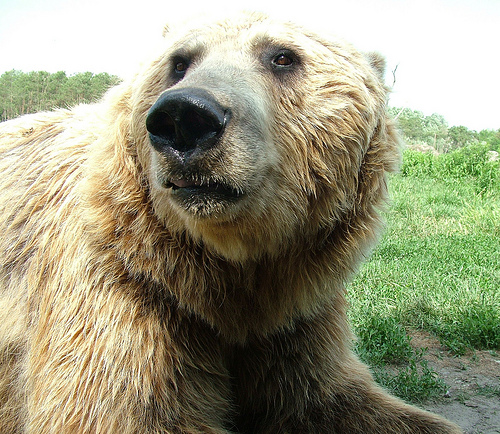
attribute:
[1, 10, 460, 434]
bear — brown, large, staring, curious, looking, wild, nice looking, cute, animal, alone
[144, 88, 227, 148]
nose — large, black, wet, big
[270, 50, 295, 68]
eye — small, brown, left eye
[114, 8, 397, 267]
head — large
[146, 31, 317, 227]
face — large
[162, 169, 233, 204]
mouth — slightly open, wet, closed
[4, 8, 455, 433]
hair — brown, long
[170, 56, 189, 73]
eye — right eye, mournful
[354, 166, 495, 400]
grass — thick, green, patchy, healthy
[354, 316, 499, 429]
dirt — patchy, path, clear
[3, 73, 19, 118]
tree — in distance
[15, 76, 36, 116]
tree — in distance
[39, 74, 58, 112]
tree — in distance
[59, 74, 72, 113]
tree — green, in distance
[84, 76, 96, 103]
tree — green, in distance, in background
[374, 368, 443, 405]
grass patch — small, green, clear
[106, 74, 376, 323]
neck — over-sized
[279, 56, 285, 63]
spot — black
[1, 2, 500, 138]
sky — clear